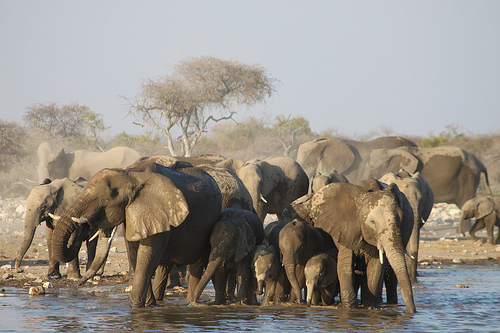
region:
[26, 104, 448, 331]
a group of elephants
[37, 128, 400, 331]
different size of elephants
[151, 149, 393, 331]
small elephants next to large elephants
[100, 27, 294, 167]
a tree with leaves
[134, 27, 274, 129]
a tree with brown leaves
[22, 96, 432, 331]
elephants in the water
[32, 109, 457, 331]
a group of elephants in the water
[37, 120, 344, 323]
a big elephant with big tusks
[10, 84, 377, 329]
elephants drinking the water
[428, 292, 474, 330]
a body of water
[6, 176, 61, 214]
gray elephant by river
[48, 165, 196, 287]
gray elephant by river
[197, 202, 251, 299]
young gray elephant by river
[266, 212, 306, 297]
young gray elephant by river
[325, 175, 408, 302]
gray elephant by river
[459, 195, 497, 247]
young gray elephant by river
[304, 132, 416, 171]
adult gray elephant by river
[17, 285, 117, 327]
brown river near elephants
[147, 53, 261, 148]
brown tree without leaves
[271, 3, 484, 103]
blue sky without clouds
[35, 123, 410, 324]
elephants bathing in water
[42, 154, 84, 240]
elephant has two white tusks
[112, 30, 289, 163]
tall trees behind elephants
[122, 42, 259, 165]
tall trees are bare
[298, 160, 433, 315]
elephant is wet in water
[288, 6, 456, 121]
sky is hazy and overcast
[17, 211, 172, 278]
ground behind elephants is rocky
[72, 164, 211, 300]
elephant is brown and grey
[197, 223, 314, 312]
young elephants with parents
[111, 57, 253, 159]
trees have gnarled branches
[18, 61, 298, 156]
brown african trees in the background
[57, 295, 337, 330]
muddy pond water in africa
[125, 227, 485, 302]
numerous elephant trunks in water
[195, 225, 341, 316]
baby elephants drinking water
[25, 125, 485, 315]
a herd of elephants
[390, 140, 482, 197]
a partially wet elephant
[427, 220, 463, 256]
dry dirt and rocks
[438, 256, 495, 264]
wet mud on the shore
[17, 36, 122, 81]
hazy blue-gray sky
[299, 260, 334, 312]
a baby elephant with a dry face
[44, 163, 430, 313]
many elephants in water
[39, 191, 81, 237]
elephant has two white tusks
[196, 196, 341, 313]
young elephants with their parents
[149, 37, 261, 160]
bare trees behind elephants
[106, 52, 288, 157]
bare trees with gnarled branches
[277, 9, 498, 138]
sky is hazy and blue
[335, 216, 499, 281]
ground behind elephants is bare and red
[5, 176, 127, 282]
rocky ground behind elephants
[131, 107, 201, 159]
thick trunks on trees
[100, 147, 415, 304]
elephants are wet